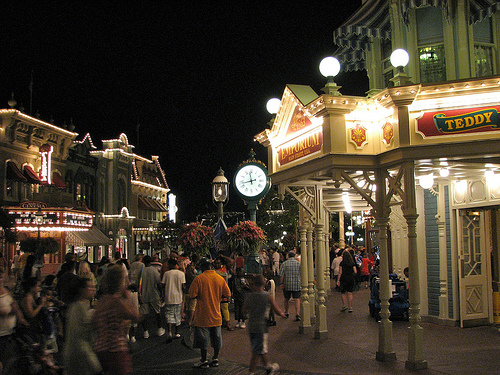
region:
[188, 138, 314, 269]
a black clock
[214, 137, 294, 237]
a black clock outside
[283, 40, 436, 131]
lights on top of a building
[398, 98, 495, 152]
a teddy sign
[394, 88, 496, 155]
a teddy sign on a building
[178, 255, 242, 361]
a man wearing a orange shirt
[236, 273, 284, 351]
a child wearing a tank top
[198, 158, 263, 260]
a tall street light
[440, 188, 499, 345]
a white door on a building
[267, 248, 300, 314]
a person wearing a plaid shirt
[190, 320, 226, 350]
Man is wearing shorts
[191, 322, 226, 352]
Man is wearing blue shorts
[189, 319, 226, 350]
Man is wearing denim shorts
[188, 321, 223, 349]
Man is wearing blue denim shorts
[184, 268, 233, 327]
Man is wearing a shirt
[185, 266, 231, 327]
Man is wearing an orange shirt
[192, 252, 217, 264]
Man is wearing a hat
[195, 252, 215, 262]
Man is wearing a hat backwards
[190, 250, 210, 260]
Man has on hat backwards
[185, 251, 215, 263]
Man is wearing a backwards hat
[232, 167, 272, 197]
a clock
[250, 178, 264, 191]
numbers on the clock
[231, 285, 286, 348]
a boy walking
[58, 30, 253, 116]
the sky is dark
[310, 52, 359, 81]
lights on the building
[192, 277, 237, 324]
an orange shirt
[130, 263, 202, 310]
people in the crowd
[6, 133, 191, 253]
the building is tall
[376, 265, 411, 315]
a pole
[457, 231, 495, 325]
the door is white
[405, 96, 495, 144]
a sign that says teddy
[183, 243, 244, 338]
a man wearing a yellow shirt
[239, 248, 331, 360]
a boy wearing shorts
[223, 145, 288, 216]
a tall clock on the side of the building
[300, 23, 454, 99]
two lights on a building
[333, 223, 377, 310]
a woman with all black on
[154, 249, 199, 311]
a man with a white t shirt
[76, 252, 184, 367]
a person with red clothes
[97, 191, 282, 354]
lots of people in town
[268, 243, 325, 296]
a man with a blue shirt on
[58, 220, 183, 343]
people at the street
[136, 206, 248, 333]
people at the street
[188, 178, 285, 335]
people at the street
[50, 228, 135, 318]
people at the street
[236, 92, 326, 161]
lights illuminated from the stores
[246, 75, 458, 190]
lights illuminated from the stores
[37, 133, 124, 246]
lights illuminated from the stores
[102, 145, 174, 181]
lights illuminated from the stores